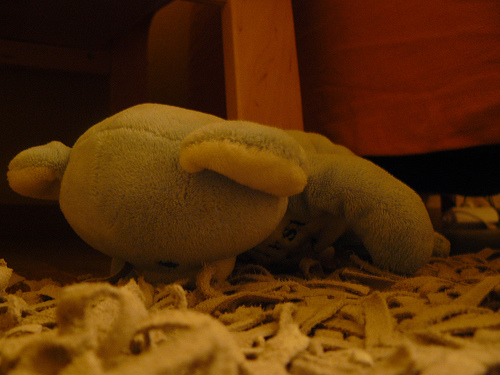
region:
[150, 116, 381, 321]
A stuffed toy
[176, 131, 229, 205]
A stuffed toy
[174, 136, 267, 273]
A stuffed toy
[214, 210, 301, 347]
A stuffed toy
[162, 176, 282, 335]
A stuffed toy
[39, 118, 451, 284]
bear is face down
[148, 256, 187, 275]
bear has black eye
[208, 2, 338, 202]
leg of chair behind bear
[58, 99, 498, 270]
bear is olive green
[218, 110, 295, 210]
bear has plush ear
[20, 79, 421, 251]
bear is plush and fluffy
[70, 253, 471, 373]
floor is stringy and white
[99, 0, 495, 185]
chair is cherry brown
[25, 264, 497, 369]
floor is curly and white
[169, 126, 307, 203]
bear has white and green ear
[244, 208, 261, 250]
teddy bear facing down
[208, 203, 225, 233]
teddy bear facing down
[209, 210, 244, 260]
teddy bear facing down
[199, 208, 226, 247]
teddy bear facing down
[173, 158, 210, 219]
teddy bear facing down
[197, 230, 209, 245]
teddy bear facing down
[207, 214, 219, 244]
teddy bear facing down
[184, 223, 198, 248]
teddy bear facing down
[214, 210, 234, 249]
teddy bear facing down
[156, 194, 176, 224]
teddy bear facing down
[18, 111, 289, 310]
teddy bear is face down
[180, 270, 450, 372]
strange rug has large threads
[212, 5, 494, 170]
wood dresser is light brown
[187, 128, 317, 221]
teddy bear has white ears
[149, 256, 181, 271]
bear has black eyes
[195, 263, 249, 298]
teddy bear has white nose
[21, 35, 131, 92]
wood panel on the wall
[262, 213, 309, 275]
bear has writing on tummy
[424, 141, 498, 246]
dark under the dresser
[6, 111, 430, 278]
teddy bear has very short fur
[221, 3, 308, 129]
brown wooden chair leg behind the teddy bear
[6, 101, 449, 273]
tan colored teddy bear on rug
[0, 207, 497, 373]
tan colored rug under teddy bear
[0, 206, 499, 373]
rug is leather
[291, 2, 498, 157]
red fabric behind teddy bear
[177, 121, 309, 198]
teddy bear ear is tan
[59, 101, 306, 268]
ear attached to head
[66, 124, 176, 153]
straight seam on teddy bear head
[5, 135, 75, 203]
teddy bear ears are two-tone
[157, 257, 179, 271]
teddy bear has a black eye